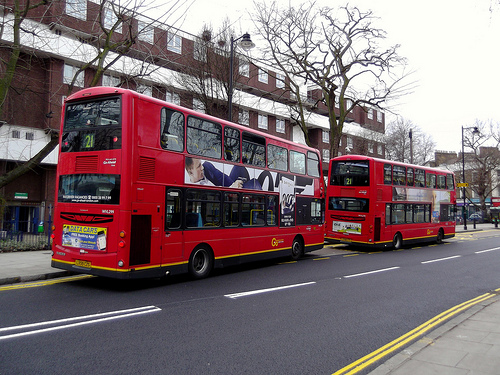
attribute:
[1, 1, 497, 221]
trees — several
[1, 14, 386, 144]
trim — white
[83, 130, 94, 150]
number 21 — route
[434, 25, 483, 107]
clouds — white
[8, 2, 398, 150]
brick building — red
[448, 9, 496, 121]
clouds — WHITE, IN SKY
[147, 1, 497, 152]
sky — blue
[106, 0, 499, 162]
clouds — white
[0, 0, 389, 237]
building — long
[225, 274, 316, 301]
line —  white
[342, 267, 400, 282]
line —  white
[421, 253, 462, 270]
line —  white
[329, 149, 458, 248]
bus — red,  second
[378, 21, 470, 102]
sky — blue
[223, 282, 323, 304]
dividers — white, dashed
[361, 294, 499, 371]
sidewalk — cement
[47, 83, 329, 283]
bus — red, two-level, first, black, in line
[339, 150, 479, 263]
bus — red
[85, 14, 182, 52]
windows — row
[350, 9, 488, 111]
clouds — white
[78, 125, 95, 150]
number — green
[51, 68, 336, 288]
bus — first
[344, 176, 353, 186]
21 —  green 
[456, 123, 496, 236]
tree — bare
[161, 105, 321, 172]
windows — row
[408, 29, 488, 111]
sky — blue